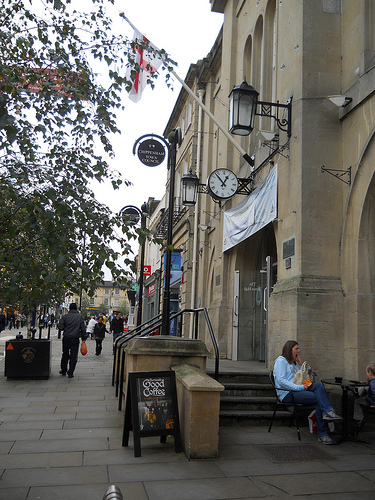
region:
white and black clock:
[208, 168, 238, 196]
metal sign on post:
[137, 136, 166, 166]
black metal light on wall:
[226, 83, 294, 139]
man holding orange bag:
[58, 303, 89, 376]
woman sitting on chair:
[279, 339, 337, 446]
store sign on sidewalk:
[124, 374, 181, 451]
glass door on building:
[237, 255, 272, 369]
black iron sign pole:
[166, 135, 170, 333]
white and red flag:
[122, 33, 160, 99]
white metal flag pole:
[123, 18, 254, 173]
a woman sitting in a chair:
[256, 324, 360, 445]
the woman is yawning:
[273, 334, 311, 368]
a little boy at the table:
[341, 349, 373, 439]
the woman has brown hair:
[274, 334, 300, 360]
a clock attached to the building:
[191, 154, 255, 212]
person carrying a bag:
[35, 266, 94, 390]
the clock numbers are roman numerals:
[203, 161, 237, 203]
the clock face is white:
[182, 153, 252, 211]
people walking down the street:
[58, 280, 156, 383]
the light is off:
[201, 67, 300, 143]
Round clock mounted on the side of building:
[208, 166, 241, 198]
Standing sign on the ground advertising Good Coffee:
[125, 371, 185, 456]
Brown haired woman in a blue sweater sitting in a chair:
[273, 340, 341, 443]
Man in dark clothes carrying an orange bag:
[58, 302, 88, 377]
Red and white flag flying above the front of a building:
[111, 12, 255, 171]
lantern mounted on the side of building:
[228, 76, 290, 142]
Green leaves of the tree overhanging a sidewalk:
[1, 1, 150, 326]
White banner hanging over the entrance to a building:
[216, 165, 282, 248]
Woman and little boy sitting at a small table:
[272, 338, 373, 445]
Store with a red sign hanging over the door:
[141, 265, 160, 323]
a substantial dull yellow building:
[164, 0, 371, 458]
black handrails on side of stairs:
[107, 305, 282, 426]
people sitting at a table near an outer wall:
[266, 271, 374, 446]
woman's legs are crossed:
[272, 380, 343, 446]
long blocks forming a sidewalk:
[2, 321, 374, 498]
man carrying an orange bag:
[57, 302, 88, 379]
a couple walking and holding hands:
[94, 309, 125, 355]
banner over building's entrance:
[216, 154, 280, 365]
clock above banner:
[207, 161, 281, 251]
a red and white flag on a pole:
[117, 10, 253, 168]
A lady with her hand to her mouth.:
[253, 343, 317, 364]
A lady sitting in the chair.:
[262, 341, 336, 447]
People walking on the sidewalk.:
[44, 290, 130, 381]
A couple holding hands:
[84, 309, 131, 356]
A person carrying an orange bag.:
[57, 297, 95, 381]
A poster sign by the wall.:
[119, 365, 184, 452]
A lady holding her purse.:
[284, 360, 319, 395]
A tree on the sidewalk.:
[7, 204, 58, 398]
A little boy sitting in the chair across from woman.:
[347, 359, 373, 422]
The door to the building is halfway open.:
[246, 257, 279, 359]